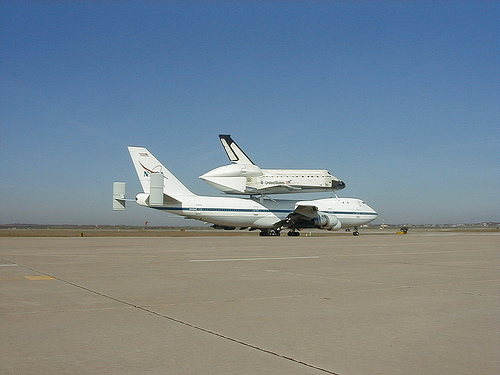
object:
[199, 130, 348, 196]
shittle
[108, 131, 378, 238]
airplane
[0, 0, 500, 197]
clouds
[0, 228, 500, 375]
runway.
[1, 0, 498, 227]
blue sky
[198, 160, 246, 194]
protector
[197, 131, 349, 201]
small plane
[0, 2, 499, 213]
clouds